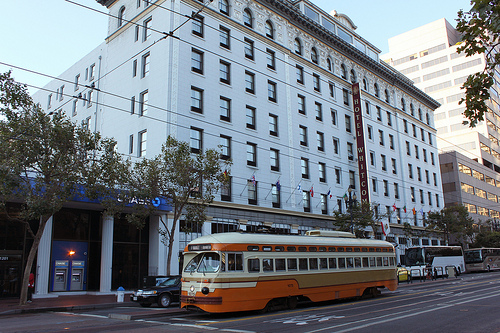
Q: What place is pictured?
A: It is a hotel.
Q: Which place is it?
A: It is a hotel.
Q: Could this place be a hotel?
A: Yes, it is a hotel.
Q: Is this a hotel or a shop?
A: It is a hotel.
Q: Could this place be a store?
A: No, it is a hotel.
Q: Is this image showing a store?
A: No, the picture is showing a hotel.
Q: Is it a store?
A: No, it is a hotel.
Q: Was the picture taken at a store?
A: No, the picture was taken in a hotel.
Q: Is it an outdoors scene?
A: Yes, it is outdoors.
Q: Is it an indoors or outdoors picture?
A: It is outdoors.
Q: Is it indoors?
A: No, it is outdoors.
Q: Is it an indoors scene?
A: No, it is outdoors.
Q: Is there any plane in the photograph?
A: No, there are no airplanes.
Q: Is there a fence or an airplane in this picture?
A: No, there are no airplanes or fences.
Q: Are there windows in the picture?
A: Yes, there is a window.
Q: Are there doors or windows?
A: Yes, there is a window.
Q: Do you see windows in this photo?
A: Yes, there is a window.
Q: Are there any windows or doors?
A: Yes, there is a window.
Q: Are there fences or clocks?
A: No, there are no fences or clocks.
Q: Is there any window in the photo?
A: Yes, there is a window.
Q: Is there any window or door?
A: Yes, there is a window.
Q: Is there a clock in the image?
A: No, there are no clocks.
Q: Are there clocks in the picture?
A: No, there are no clocks.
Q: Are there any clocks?
A: No, there are no clocks.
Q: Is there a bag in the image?
A: No, there are no bags.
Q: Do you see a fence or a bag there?
A: No, there are no bags or fences.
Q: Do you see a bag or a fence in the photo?
A: No, there are no bags or fences.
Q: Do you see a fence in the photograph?
A: No, there are no fences.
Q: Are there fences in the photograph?
A: No, there are no fences.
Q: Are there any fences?
A: No, there are no fences.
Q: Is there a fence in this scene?
A: No, there are no fences.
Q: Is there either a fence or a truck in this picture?
A: No, there are no fences or trucks.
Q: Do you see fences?
A: No, there are no fences.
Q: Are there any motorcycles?
A: No, there are no motorcycles.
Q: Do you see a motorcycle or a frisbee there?
A: No, there are no motorcycles or frisbees.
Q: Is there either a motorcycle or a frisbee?
A: No, there are no motorcycles or frisbees.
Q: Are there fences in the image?
A: No, there are no fences.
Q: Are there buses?
A: Yes, there is a bus.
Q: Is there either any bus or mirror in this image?
A: Yes, there is a bus.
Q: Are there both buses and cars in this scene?
A: Yes, there are both a bus and a car.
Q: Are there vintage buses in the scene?
A: Yes, there is a vintage bus.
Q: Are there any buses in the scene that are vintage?
A: Yes, there is a vintage bus.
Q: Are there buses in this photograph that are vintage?
A: Yes, there is a bus that is vintage.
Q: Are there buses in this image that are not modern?
A: Yes, there is a vintage bus.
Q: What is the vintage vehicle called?
A: The vehicle is a bus.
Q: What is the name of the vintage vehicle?
A: The vehicle is a bus.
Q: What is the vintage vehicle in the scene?
A: The vehicle is a bus.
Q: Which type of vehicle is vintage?
A: The vehicle is a bus.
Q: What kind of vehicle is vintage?
A: The vehicle is a bus.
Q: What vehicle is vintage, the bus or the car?
A: The bus is vintage.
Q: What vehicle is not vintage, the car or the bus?
A: The car is not vintage.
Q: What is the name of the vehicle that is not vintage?
A: The vehicle is a car.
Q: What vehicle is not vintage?
A: The vehicle is a car.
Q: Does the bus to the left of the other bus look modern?
A: No, the bus is vintage.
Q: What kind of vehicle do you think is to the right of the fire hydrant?
A: The vehicle is a bus.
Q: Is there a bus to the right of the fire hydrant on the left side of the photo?
A: Yes, there is a bus to the right of the fire hydrant.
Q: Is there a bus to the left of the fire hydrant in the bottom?
A: No, the bus is to the right of the fire hydrant.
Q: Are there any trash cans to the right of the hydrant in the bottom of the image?
A: No, there is a bus to the right of the fire hydrant.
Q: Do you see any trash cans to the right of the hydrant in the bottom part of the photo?
A: No, there is a bus to the right of the fire hydrant.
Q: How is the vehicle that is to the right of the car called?
A: The vehicle is a bus.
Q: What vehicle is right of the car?
A: The vehicle is a bus.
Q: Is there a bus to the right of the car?
A: Yes, there is a bus to the right of the car.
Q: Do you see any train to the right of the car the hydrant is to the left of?
A: No, there is a bus to the right of the car.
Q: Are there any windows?
A: Yes, there is a window.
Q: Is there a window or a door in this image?
A: Yes, there is a window.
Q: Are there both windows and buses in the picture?
A: Yes, there are both a window and a bus.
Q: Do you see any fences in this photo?
A: No, there are no fences.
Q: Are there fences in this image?
A: No, there are no fences.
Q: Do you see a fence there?
A: No, there are no fences.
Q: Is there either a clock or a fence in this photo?
A: No, there are no fences or clocks.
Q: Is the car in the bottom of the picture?
A: Yes, the car is in the bottom of the image.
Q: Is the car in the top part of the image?
A: No, the car is in the bottom of the image.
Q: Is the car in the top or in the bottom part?
A: The car is in the bottom of the image.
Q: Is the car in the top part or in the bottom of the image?
A: The car is in the bottom of the image.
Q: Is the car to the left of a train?
A: No, the car is to the left of the bus.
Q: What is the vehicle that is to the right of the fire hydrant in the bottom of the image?
A: The vehicle is a car.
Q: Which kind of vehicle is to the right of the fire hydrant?
A: The vehicle is a car.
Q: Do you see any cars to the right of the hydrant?
A: Yes, there is a car to the right of the hydrant.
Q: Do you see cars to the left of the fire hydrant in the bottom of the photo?
A: No, the car is to the right of the hydrant.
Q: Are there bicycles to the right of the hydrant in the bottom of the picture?
A: No, there is a car to the right of the fire hydrant.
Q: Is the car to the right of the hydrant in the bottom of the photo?
A: Yes, the car is to the right of the hydrant.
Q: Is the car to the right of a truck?
A: No, the car is to the right of the hydrant.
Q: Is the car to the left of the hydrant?
A: No, the car is to the right of the hydrant.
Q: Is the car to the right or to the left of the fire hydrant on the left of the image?
A: The car is to the right of the hydrant.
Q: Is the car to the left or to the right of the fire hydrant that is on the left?
A: The car is to the right of the hydrant.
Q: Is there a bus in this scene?
A: Yes, there is a bus.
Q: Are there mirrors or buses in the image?
A: Yes, there is a bus.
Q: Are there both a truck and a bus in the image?
A: No, there is a bus but no trucks.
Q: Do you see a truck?
A: No, there are no trucks.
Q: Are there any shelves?
A: No, there are no shelves.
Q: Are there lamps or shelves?
A: No, there are no shelves or lamps.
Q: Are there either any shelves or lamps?
A: No, there are no shelves or lamps.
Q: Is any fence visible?
A: No, there are no fences.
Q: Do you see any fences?
A: No, there are no fences.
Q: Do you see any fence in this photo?
A: No, there are no fences.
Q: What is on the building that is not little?
A: The sign is on the building.